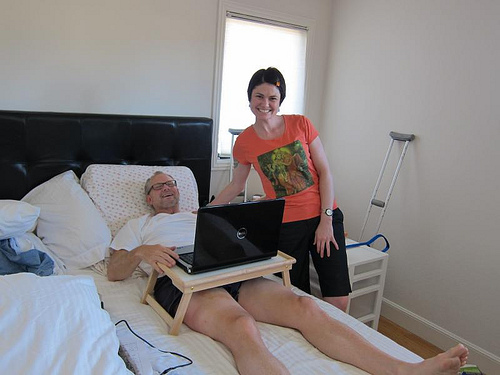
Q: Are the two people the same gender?
A: No, they are both male and female.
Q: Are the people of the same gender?
A: No, they are both male and female.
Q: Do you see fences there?
A: No, there are no fences.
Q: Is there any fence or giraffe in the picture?
A: No, there are no fences or giraffes.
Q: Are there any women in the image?
A: Yes, there is a woman.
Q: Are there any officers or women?
A: Yes, there is a woman.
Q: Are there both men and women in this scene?
A: Yes, there are both a woman and men.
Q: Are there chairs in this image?
A: No, there are no chairs.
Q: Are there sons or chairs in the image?
A: No, there are no chairs or sons.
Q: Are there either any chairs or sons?
A: No, there are no chairs or sons.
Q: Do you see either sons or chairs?
A: No, there are no chairs or sons.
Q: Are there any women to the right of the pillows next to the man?
A: Yes, there is a woman to the right of the pillows.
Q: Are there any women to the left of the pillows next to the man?
A: No, the woman is to the right of the pillows.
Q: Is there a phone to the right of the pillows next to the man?
A: No, there is a woman to the right of the pillows.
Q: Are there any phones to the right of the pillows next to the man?
A: No, there is a woman to the right of the pillows.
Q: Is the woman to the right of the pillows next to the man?
A: Yes, the woman is to the right of the pillows.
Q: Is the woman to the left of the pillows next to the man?
A: No, the woman is to the right of the pillows.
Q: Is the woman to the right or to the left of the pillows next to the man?
A: The woman is to the right of the pillows.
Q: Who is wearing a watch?
A: The woman is wearing a watch.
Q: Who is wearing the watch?
A: The woman is wearing a watch.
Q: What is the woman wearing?
A: The woman is wearing a watch.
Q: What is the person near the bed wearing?
A: The woman is wearing a watch.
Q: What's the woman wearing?
A: The woman is wearing a watch.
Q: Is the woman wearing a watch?
A: Yes, the woman is wearing a watch.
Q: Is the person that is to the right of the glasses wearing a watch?
A: Yes, the woman is wearing a watch.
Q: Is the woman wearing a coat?
A: No, the woman is wearing a watch.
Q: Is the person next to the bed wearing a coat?
A: No, the woman is wearing a watch.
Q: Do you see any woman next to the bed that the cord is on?
A: Yes, there is a woman next to the bed.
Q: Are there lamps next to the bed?
A: No, there is a woman next to the bed.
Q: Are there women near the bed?
A: Yes, there is a woman near the bed.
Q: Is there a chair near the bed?
A: No, there is a woman near the bed.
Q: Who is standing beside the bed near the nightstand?
A: The woman is standing beside the bed.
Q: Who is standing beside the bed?
A: The woman is standing beside the bed.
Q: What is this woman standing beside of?
A: The woman is standing beside the bed.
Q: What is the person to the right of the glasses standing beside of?
A: The woman is standing beside the bed.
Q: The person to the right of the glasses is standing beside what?
A: The woman is standing beside the bed.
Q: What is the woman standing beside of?
A: The woman is standing beside the bed.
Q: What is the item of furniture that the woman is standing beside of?
A: The piece of furniture is a bed.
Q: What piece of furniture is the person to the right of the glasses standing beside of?
A: The woman is standing beside the bed.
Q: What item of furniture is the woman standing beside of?
A: The woman is standing beside the bed.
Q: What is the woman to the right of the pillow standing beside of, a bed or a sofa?
A: The woman is standing beside a bed.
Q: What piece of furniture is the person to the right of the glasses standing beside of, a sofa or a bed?
A: The woman is standing beside a bed.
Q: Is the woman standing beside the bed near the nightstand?
A: Yes, the woman is standing beside the bed.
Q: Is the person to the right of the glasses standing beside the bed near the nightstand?
A: Yes, the woman is standing beside the bed.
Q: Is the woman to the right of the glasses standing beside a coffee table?
A: No, the woman is standing beside the bed.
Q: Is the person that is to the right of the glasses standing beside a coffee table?
A: No, the woman is standing beside the bed.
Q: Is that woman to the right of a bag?
A: No, the woman is to the right of the pillow.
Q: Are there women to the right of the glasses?
A: Yes, there is a woman to the right of the glasses.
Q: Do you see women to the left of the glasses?
A: No, the woman is to the right of the glasses.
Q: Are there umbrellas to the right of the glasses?
A: No, there is a woman to the right of the glasses.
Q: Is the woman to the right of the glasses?
A: Yes, the woman is to the right of the glasses.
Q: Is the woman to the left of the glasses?
A: No, the woman is to the right of the glasses.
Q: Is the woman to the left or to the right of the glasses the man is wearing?
A: The woman is to the right of the glasses.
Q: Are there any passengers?
A: No, there are no passengers.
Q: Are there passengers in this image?
A: No, there are no passengers.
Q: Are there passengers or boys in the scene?
A: No, there are no passengers or boys.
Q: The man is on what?
A: The man is on the bed.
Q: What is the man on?
A: The man is on the bed.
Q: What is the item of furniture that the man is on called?
A: The piece of furniture is a bed.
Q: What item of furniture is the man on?
A: The man is on the bed.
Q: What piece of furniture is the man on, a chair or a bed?
A: The man is on a bed.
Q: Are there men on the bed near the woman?
A: Yes, there is a man on the bed.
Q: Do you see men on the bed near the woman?
A: Yes, there is a man on the bed.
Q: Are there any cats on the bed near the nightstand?
A: No, there is a man on the bed.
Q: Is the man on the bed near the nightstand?
A: Yes, the man is on the bed.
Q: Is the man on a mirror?
A: No, the man is on the bed.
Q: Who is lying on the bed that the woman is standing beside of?
A: The man is lying on the bed.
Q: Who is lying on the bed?
A: The man is lying on the bed.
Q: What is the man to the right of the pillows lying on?
A: The man is lying on the bed.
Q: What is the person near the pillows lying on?
A: The man is lying on the bed.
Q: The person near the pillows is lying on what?
A: The man is lying on the bed.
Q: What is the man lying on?
A: The man is lying on the bed.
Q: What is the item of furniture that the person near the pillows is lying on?
A: The piece of furniture is a bed.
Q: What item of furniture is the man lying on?
A: The man is lying on the bed.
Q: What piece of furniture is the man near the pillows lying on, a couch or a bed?
A: The man is lying on a bed.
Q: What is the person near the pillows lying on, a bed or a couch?
A: The man is lying on a bed.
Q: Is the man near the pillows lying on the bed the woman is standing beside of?
A: Yes, the man is lying on the bed.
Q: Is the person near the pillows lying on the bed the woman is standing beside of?
A: Yes, the man is lying on the bed.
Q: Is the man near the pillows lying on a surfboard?
A: No, the man is lying on the bed.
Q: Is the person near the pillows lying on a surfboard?
A: No, the man is lying on the bed.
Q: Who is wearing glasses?
A: The man is wearing glasses.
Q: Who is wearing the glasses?
A: The man is wearing glasses.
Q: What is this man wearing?
A: The man is wearing glasses.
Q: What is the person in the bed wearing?
A: The man is wearing glasses.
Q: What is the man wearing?
A: The man is wearing glasses.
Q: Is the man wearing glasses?
A: Yes, the man is wearing glasses.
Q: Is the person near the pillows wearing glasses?
A: Yes, the man is wearing glasses.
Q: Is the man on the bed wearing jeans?
A: No, the man is wearing glasses.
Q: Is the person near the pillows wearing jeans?
A: No, the man is wearing glasses.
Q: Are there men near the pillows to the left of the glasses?
A: Yes, there is a man near the pillows.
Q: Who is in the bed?
A: The man is in the bed.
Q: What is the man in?
A: The man is in the bed.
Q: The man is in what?
A: The man is in the bed.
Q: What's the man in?
A: The man is in the bed.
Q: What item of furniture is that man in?
A: The man is in the bed.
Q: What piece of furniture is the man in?
A: The man is in the bed.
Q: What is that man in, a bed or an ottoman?
A: The man is in a bed.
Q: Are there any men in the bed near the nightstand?
A: Yes, there is a man in the bed.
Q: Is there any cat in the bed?
A: No, there is a man in the bed.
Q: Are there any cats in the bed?
A: No, there is a man in the bed.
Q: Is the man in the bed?
A: Yes, the man is in the bed.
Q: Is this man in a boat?
A: No, the man is in the bed.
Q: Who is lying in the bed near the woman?
A: The man is lying in the bed.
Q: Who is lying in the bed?
A: The man is lying in the bed.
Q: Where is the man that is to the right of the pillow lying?
A: The man is lying in the bed.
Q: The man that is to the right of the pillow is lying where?
A: The man is lying in the bed.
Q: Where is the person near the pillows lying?
A: The man is lying in the bed.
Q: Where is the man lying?
A: The man is lying in the bed.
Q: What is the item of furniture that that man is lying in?
A: The piece of furniture is a bed.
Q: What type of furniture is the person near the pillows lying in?
A: The man is lying in the bed.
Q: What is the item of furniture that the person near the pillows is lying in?
A: The piece of furniture is a bed.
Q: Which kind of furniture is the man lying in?
A: The man is lying in the bed.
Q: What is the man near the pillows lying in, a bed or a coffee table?
A: The man is lying in a bed.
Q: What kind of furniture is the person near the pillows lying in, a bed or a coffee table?
A: The man is lying in a bed.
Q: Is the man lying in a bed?
A: Yes, the man is lying in a bed.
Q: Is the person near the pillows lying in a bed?
A: Yes, the man is lying in a bed.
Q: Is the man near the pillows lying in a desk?
A: No, the man is lying in a bed.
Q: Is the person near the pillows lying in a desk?
A: No, the man is lying in a bed.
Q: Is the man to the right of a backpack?
A: No, the man is to the right of the pillow.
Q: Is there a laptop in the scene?
A: Yes, there is a laptop.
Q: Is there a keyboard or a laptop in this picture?
A: Yes, there is a laptop.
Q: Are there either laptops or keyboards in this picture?
A: Yes, there is a laptop.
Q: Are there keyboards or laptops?
A: Yes, there is a laptop.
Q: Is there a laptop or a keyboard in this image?
A: Yes, there is a laptop.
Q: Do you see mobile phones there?
A: No, there are no mobile phones.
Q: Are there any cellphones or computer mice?
A: No, there are no cellphones or computer mice.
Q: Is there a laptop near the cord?
A: Yes, there is a laptop near the cord.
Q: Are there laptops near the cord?
A: Yes, there is a laptop near the cord.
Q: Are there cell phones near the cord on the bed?
A: No, there is a laptop near the wire.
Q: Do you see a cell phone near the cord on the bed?
A: No, there is a laptop near the wire.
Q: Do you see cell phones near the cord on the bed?
A: No, there is a laptop near the wire.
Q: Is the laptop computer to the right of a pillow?
A: Yes, the laptop computer is to the right of a pillow.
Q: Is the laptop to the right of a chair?
A: No, the laptop is to the right of a pillow.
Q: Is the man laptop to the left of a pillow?
A: No, the laptop is to the right of a pillow.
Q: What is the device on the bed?
A: The device is a laptop.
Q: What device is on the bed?
A: The device is a laptop.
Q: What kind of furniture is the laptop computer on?
A: The laptop computer is on the bed.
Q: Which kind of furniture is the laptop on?
A: The laptop computer is on the bed.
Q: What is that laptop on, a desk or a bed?
A: The laptop is on a bed.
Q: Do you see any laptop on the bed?
A: Yes, there is a laptop on the bed.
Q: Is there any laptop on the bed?
A: Yes, there is a laptop on the bed.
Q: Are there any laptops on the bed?
A: Yes, there is a laptop on the bed.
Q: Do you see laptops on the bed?
A: Yes, there is a laptop on the bed.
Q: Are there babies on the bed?
A: No, there is a laptop on the bed.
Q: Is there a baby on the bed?
A: No, there is a laptop on the bed.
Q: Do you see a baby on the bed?
A: No, there is a laptop on the bed.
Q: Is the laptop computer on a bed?
A: Yes, the laptop computer is on a bed.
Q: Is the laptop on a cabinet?
A: No, the laptop is on a bed.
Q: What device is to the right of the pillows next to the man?
A: The device is a laptop.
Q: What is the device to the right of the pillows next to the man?
A: The device is a laptop.